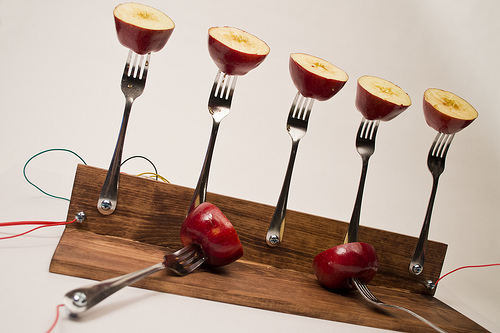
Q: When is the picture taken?
A: Daytime.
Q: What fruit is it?
A: Apple.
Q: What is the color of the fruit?
A: Red.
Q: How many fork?
A: 7.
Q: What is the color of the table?
A: Brown.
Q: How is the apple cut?
A: Into halves.